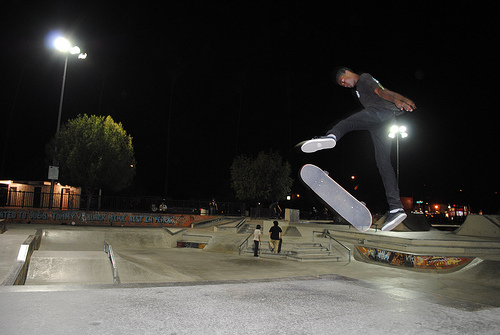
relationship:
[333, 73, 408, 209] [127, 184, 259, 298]
skateboarder at park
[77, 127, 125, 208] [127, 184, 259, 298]
tree by park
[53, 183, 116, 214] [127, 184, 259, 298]
railing at park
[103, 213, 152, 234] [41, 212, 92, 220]
graffiti on wall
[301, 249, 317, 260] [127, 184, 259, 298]
steps in park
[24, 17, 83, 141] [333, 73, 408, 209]
street light behind skateboarder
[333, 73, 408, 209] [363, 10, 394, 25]
skateboarder in air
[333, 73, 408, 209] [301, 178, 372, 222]
skateboarder holding skateboard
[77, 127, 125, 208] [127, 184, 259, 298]
tree next to park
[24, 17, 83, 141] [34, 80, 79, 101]
street light on pole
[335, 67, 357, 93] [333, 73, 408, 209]
head of skateboarder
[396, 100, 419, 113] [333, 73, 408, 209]
hand of skateboarder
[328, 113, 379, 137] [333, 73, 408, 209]
leg of skateboarder